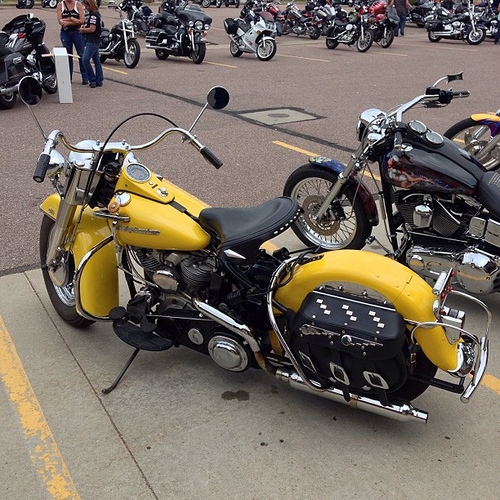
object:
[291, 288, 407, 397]
bag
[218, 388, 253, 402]
spot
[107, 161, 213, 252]
tank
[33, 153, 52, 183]
grip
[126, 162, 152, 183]
gauge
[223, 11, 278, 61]
bike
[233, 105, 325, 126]
cement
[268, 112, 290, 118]
grate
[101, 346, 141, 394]
stand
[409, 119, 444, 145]
gauges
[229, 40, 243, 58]
tires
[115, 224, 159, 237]
logo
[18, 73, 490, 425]
bike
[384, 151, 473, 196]
design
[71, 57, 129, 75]
lines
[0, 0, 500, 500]
ground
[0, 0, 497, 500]
parking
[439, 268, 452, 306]
lights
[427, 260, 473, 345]
piece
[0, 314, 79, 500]
line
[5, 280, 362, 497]
space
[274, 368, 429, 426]
tailpipe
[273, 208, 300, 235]
studs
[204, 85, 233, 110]
mirror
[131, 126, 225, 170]
handlebar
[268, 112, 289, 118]
top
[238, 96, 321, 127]
surface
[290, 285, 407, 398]
case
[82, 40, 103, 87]
jeans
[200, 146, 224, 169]
black tip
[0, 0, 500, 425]
lot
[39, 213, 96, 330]
front tire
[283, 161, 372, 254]
front tire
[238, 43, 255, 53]
motorized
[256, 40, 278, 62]
front tire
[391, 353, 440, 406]
rear tire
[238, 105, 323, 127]
covering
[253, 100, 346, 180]
lot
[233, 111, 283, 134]
tar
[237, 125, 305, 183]
crevice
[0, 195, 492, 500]
lanes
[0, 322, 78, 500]
strip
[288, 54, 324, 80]
empty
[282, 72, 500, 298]
bike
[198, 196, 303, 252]
seat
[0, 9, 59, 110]
bikes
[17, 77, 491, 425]
display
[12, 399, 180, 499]
lot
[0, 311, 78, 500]
mark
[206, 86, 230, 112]
round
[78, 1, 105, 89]
woman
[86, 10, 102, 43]
t-shirt